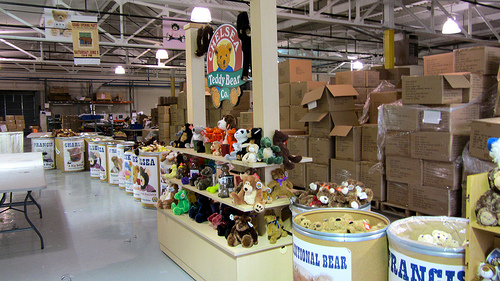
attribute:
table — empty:
[0, 152, 47, 249]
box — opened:
[384, 69, 472, 107]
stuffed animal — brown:
[272, 131, 302, 171]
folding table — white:
[0, 152, 49, 250]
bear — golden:
[262, 212, 288, 241]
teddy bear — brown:
[223, 214, 260, 246]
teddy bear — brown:
[193, 162, 213, 192]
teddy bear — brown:
[266, 165, 300, 202]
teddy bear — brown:
[265, 209, 290, 243]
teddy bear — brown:
[270, 127, 302, 167]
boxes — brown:
[378, 125, 428, 185]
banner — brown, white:
[70, 10, 104, 66]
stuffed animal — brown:
[227, 212, 257, 249]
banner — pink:
[149, 13, 196, 65]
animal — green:
[258, 135, 285, 170]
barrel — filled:
[53, 137, 86, 171]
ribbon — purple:
[274, 171, 296, 187]